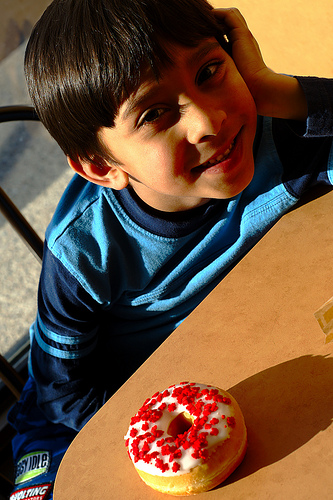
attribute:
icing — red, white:
[124, 380, 234, 474]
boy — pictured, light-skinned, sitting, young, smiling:
[8, 0, 329, 499]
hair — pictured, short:
[23, 0, 233, 165]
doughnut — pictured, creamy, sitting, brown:
[125, 380, 247, 496]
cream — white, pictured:
[126, 380, 237, 475]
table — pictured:
[51, 186, 333, 498]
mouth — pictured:
[187, 123, 247, 178]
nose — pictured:
[187, 88, 228, 144]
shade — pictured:
[247, 352, 331, 466]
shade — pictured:
[141, 1, 332, 210]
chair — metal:
[2, 106, 85, 399]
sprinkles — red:
[123, 382, 236, 473]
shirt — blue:
[8, 77, 330, 429]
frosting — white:
[126, 382, 233, 476]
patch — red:
[4, 483, 51, 499]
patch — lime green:
[10, 449, 48, 484]